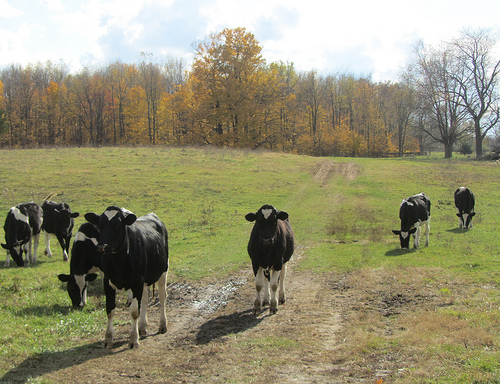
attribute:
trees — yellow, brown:
[116, 37, 337, 154]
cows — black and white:
[0, 173, 480, 320]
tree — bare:
[449, 39, 499, 154]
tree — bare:
[411, 50, 468, 156]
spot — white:
[261, 207, 271, 218]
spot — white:
[104, 207, 117, 218]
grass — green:
[2, 146, 497, 381]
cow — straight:
[236, 204, 312, 322]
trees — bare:
[375, 24, 497, 204]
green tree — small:
[460, 143, 470, 156]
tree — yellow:
[326, 118, 350, 153]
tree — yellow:
[366, 117, 393, 154]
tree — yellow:
[253, 70, 293, 146]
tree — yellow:
[203, 23, 263, 146]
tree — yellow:
[160, 77, 202, 142]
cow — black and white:
[241, 201, 298, 315]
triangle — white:
[260, 207, 274, 219]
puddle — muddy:
[189, 272, 242, 317]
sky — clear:
[283, 15, 432, 72]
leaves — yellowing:
[0, 28, 452, 153]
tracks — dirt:
[154, 152, 403, 382]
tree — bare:
[405, 36, 468, 166]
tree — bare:
[440, 31, 481, 141]